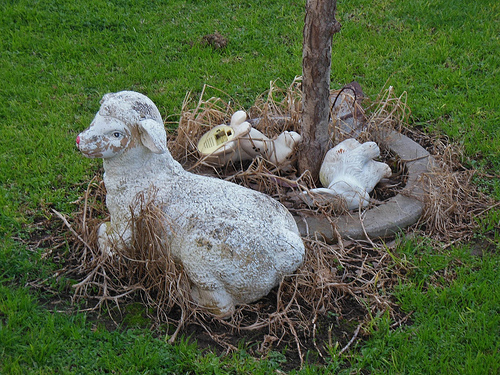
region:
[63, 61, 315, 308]
STONE SHEEP LAYING ON STICKS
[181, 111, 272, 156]
YELLOW BOTTOM OF PLASTIC BUNNY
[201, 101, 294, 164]
WHITE PLASTIC BUNNY LAYING ON STICKS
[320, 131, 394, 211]
WHITE PLASTIC BUNNY LAYING ON STICKS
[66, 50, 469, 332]
BROWN DEAD STICKS UNDER PLASTIC ANIMALS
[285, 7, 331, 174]
THIN BROWN TREE TRUNK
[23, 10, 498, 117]
SHORT MOWED GREEN GRASS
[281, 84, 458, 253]
ROUND STONE WALL AROUND TREE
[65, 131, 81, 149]
RED NOSE ON STONE SHEEP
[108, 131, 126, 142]
SMALL DARK EYE ON STONE SHEEP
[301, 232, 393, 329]
the twigs are brown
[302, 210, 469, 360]
twigs in the grass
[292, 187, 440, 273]
the barrier is stone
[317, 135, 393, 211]
the figurine is rabbit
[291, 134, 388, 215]
the figurine has fallen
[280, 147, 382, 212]
the rabbit figure in twigs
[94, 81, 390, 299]
three figurines in twigs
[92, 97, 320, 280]
the sheep figure is worn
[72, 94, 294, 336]
sheep figure in twigs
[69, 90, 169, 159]
sheep figure has pink nose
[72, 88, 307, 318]
Worn sheep decoration in the grass.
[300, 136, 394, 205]
Worn white colored rabbit decoration lying on its side.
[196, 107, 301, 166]
Small white decoration lying on its back.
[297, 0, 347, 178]
Thin gray and brown tree trunk.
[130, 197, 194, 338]
Dead weeds in the middle front of the sheep.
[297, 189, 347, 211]
Ear of a rabbit lying on its side.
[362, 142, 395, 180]
Two front paws of a side laying rabbit.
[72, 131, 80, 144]
Red nose of a sheep.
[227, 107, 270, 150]
Two white front paws of a decoration lying on its back.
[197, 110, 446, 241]
Concrete stones in circle shape around a thin tree trunk.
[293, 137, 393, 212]
White worn rabbit lying on its side.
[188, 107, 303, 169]
White decoration lying on its back near a tree.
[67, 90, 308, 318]
Worn white sheep decoration.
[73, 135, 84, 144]
Red nose on a white sheep decoration.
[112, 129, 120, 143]
Black and white eye of a sheep.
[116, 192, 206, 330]
Dead brown weeds on a white sheep.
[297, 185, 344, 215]
White worn ear of a rabbit lying on its side.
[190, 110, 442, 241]
Round paver stones around a tree trunk.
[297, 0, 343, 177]
Brown thin tree trunk.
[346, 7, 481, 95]
Green grass to the back right of a tree trunk.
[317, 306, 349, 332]
part of a ground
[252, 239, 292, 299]
part of a statue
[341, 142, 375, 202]
part of a rabbit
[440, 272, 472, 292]
part of some grass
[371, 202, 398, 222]
edge of a rock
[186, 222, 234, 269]
part of a thigh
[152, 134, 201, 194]
part of a thigh